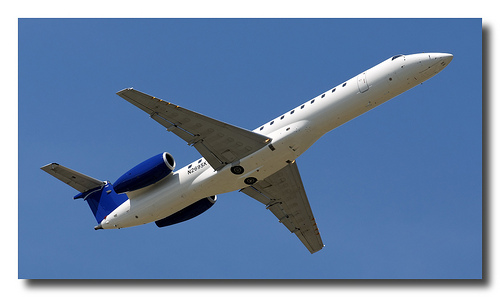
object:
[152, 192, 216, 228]
engine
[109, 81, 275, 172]
wings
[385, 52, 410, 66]
cockpit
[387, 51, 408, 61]
cockpit windshield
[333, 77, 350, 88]
windows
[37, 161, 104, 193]
wing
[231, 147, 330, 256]
wing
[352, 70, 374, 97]
door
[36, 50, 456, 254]
airplane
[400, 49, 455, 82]
nose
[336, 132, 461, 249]
clouds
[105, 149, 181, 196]
engine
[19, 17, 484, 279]
sky